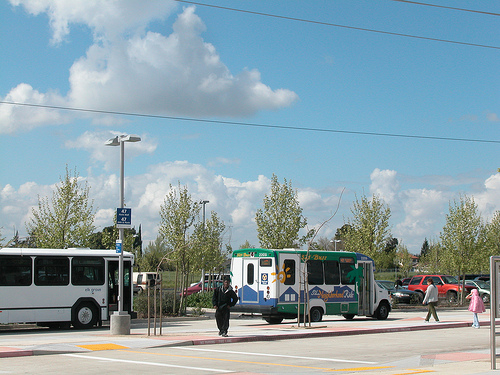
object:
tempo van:
[228, 247, 394, 324]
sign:
[489, 255, 500, 317]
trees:
[22, 164, 99, 251]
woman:
[422, 275, 443, 324]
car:
[181, 280, 224, 296]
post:
[118, 141, 126, 309]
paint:
[75, 342, 124, 352]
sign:
[113, 206, 133, 229]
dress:
[466, 290, 486, 314]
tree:
[252, 172, 309, 250]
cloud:
[1, 1, 307, 128]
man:
[210, 274, 239, 337]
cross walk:
[57, 324, 383, 374]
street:
[0, 324, 499, 374]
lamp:
[102, 133, 119, 147]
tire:
[71, 296, 98, 330]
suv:
[407, 274, 479, 306]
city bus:
[0, 246, 138, 330]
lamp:
[118, 134, 146, 143]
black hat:
[426, 277, 434, 281]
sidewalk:
[0, 310, 497, 358]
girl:
[463, 288, 488, 329]